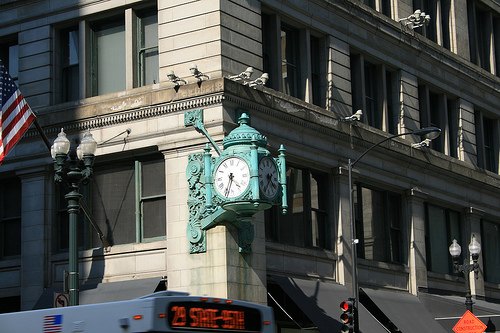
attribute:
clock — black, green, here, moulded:
[204, 129, 290, 233]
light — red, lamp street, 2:
[335, 292, 360, 328]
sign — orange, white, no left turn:
[433, 306, 479, 333]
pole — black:
[340, 124, 381, 302]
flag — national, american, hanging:
[0, 70, 61, 158]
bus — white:
[20, 297, 274, 326]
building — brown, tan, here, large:
[11, 12, 486, 293]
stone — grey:
[171, 11, 205, 51]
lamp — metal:
[44, 135, 99, 299]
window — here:
[251, 70, 476, 271]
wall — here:
[222, 12, 437, 173]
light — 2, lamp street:
[442, 230, 467, 273]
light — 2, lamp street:
[467, 229, 484, 279]